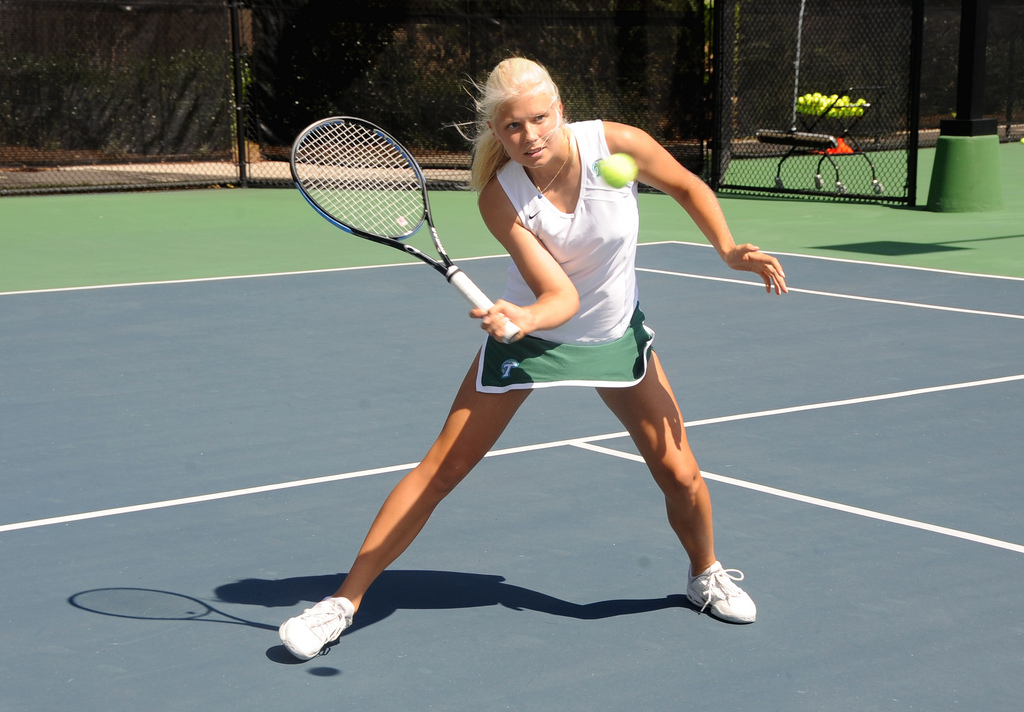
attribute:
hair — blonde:
[438, 51, 564, 193]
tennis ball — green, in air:
[598, 151, 638, 191]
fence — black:
[1, 1, 243, 197]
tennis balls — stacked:
[794, 91, 872, 121]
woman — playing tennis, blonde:
[279, 53, 785, 658]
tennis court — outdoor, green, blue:
[1, 133, 1020, 710]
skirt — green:
[476, 293, 660, 393]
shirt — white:
[492, 117, 640, 343]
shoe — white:
[277, 596, 355, 662]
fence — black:
[716, 0, 918, 206]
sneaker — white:
[684, 556, 760, 628]